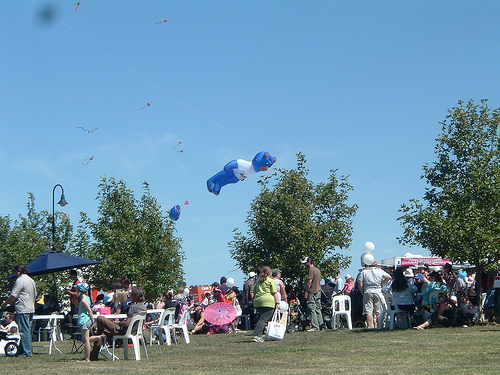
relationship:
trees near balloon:
[13, 100, 499, 273] [165, 154, 279, 224]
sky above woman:
[2, 3, 495, 220] [248, 265, 282, 343]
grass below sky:
[0, 319, 499, 375] [2, 3, 495, 220]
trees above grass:
[13, 100, 499, 273] [0, 319, 499, 375]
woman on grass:
[248, 265, 282, 343] [0, 319, 499, 375]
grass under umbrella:
[0, 319, 499, 375] [29, 246, 91, 273]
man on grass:
[6, 257, 42, 362] [0, 319, 499, 375]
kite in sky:
[169, 134, 288, 222] [204, 32, 367, 144]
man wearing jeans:
[6, 257, 42, 362] [1, 296, 51, 353]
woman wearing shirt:
[253, 279, 293, 336] [247, 271, 272, 310]